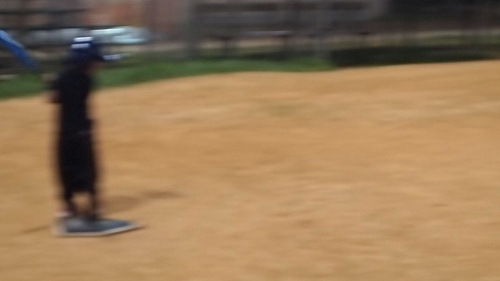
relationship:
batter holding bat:
[32, 50, 102, 223] [4, 25, 51, 87]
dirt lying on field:
[3, 58, 498, 280] [191, 40, 483, 278]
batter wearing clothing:
[32, 50, 102, 223] [44, 60, 102, 203]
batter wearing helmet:
[32, 50, 102, 223] [59, 30, 110, 68]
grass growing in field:
[4, 55, 329, 95] [1, 44, 483, 279]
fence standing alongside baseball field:
[0, 0, 499, 83] [190, 80, 462, 260]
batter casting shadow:
[2, 13, 146, 239] [68, 188, 188, 211]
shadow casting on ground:
[68, 188, 188, 211] [1, 58, 477, 255]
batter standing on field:
[32, 50, 102, 223] [0, 0, 498, 280]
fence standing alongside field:
[0, 0, 499, 83] [1, 44, 483, 279]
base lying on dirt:
[50, 212, 144, 240] [283, 100, 413, 225]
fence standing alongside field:
[75, 23, 487, 75] [1, 44, 483, 279]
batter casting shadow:
[32, 50, 102, 223] [62, 186, 187, 220]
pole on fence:
[188, 0, 200, 58] [1, 1, 498, 59]